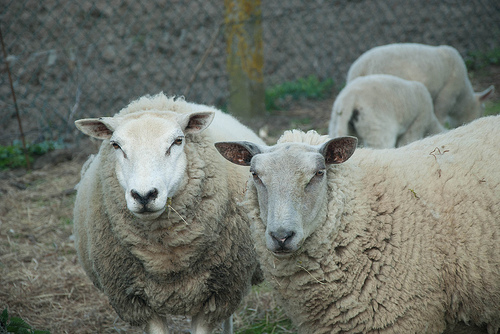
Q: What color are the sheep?
A: White.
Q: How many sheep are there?
A: Four.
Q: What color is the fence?
A: Gray.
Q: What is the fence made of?
A: Metal.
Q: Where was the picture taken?
A: In the pasture.